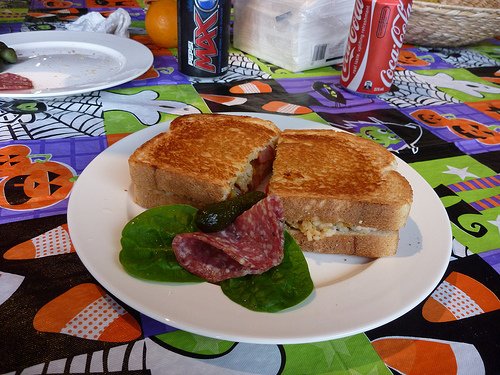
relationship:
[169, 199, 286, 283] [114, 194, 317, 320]
meat on top of lettuce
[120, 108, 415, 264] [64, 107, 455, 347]
sandwich on plate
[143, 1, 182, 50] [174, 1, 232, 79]
fruit next to can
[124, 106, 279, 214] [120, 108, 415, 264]
half of sandwich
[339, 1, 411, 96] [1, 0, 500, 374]
can on cloth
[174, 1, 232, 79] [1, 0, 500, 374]
can on cloth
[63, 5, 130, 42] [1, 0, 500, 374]
napkin on cloth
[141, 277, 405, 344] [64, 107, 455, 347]
edge of plate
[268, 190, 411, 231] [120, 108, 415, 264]
edge of sandwich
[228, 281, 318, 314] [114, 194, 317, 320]
edge of leaf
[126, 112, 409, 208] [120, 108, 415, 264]
surface of sandwich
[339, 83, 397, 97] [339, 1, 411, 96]
base of can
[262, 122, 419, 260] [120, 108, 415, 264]
half of sandwich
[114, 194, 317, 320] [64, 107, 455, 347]
lettuce on plate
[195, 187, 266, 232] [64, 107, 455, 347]
pickle on plate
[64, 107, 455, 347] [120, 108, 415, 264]
plate with sandwich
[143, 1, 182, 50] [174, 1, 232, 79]
fruit behind can